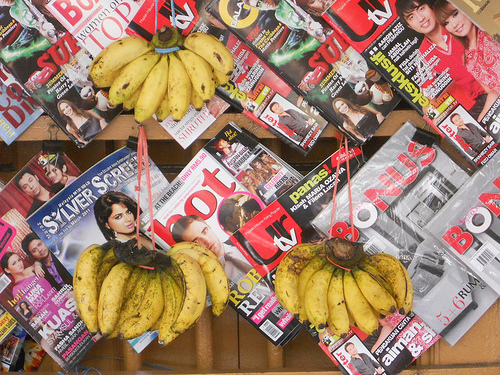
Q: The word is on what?
A: The word is on the magazine.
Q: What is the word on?
A: The word is on the magazine.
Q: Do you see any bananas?
A: Yes, there is a banana.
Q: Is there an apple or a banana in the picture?
A: Yes, there is a banana.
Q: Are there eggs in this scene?
A: No, there are no eggs.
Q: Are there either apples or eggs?
A: No, there are no eggs or apples.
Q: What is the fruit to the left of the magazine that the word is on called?
A: The fruit is a banana.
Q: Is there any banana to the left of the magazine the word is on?
A: Yes, there is a banana to the left of the magazine.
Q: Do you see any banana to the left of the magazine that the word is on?
A: Yes, there is a banana to the left of the magazine.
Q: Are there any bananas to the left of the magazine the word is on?
A: Yes, there is a banana to the left of the magazine.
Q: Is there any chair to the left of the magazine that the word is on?
A: No, there is a banana to the left of the magazine.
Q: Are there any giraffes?
A: No, there are no giraffes.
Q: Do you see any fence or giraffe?
A: No, there are no giraffes or fences.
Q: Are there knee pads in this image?
A: No, there are no knee pads.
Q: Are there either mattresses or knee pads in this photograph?
A: No, there are no knee pads or mattresses.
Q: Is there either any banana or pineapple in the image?
A: Yes, there is a banana.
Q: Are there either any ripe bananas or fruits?
A: Yes, there is a ripe banana.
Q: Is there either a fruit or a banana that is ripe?
A: Yes, the banana is ripe.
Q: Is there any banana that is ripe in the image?
A: Yes, there is a ripe banana.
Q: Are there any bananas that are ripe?
A: Yes, there is a banana that is ripe.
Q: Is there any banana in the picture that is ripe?
A: Yes, there is a banana that is ripe.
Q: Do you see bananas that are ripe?
A: Yes, there is a banana that is ripe.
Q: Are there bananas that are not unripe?
A: Yes, there is an ripe banana.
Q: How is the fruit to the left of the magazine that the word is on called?
A: The fruit is a banana.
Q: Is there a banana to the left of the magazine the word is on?
A: Yes, there is a banana to the left of the magazine.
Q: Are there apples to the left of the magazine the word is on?
A: No, there is a banana to the left of the magazine.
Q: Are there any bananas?
A: Yes, there is a banana.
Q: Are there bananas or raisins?
A: Yes, there is a banana.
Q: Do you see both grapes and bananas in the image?
A: No, there is a banana but no grapes.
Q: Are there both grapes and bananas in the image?
A: No, there is a banana but no grapes.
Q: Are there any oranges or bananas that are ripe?
A: Yes, the banana is ripe.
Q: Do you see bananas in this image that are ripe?
A: Yes, there is a ripe banana.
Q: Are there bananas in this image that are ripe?
A: Yes, there is a banana that is ripe.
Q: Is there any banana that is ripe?
A: Yes, there is a banana that is ripe.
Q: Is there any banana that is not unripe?
A: Yes, there is an ripe banana.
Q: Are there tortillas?
A: No, there are no tortillas.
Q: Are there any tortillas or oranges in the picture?
A: No, there are no tortillas or oranges.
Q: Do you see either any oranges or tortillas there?
A: No, there are no tortillas or oranges.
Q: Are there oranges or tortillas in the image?
A: No, there are no tortillas or oranges.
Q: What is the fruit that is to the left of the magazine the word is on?
A: The fruit is a banana.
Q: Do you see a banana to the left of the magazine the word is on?
A: Yes, there is a banana to the left of the magazine.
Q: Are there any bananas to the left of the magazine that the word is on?
A: Yes, there is a banana to the left of the magazine.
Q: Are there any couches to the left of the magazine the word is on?
A: No, there is a banana to the left of the magazine.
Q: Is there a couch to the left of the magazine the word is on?
A: No, there is a banana to the left of the magazine.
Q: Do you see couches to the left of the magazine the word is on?
A: No, there is a banana to the left of the magazine.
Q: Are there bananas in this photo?
A: Yes, there is a banana.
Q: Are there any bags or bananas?
A: Yes, there is a banana.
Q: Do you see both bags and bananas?
A: No, there is a banana but no bags.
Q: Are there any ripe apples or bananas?
A: Yes, there is a ripe banana.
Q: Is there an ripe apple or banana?
A: Yes, there is a ripe banana.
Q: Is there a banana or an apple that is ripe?
A: Yes, the banana is ripe.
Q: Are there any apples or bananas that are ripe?
A: Yes, the banana is ripe.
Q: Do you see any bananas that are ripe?
A: Yes, there is a ripe banana.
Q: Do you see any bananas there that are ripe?
A: Yes, there is a banana that is ripe.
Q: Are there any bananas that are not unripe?
A: Yes, there is an ripe banana.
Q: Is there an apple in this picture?
A: No, there are no apples.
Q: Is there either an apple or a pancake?
A: No, there are no apples or pancakes.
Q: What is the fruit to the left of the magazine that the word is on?
A: The fruit is a banana.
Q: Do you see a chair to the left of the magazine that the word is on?
A: No, there is a banana to the left of the magazine.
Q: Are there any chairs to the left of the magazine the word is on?
A: No, there is a banana to the left of the magazine.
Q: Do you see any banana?
A: Yes, there is a banana.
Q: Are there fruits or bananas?
A: Yes, there is a banana.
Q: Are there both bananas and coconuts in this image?
A: No, there is a banana but no coconuts.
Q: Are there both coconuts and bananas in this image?
A: No, there is a banana but no coconuts.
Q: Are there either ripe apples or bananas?
A: Yes, there is a ripe banana.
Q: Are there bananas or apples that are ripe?
A: Yes, the banana is ripe.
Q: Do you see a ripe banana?
A: Yes, there is a ripe banana.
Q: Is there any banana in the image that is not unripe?
A: Yes, there is an ripe banana.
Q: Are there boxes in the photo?
A: No, there are no boxes.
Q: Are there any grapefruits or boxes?
A: No, there are no boxes or grapefruits.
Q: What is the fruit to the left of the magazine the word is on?
A: The fruit is a banana.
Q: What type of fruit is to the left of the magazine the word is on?
A: The fruit is a banana.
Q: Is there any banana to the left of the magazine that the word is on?
A: Yes, there is a banana to the left of the magazine.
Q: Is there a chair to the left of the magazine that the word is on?
A: No, there is a banana to the left of the magazine.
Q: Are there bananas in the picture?
A: Yes, there are bananas.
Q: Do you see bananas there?
A: Yes, there are bananas.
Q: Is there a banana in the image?
A: Yes, there are bananas.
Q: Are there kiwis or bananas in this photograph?
A: Yes, there are bananas.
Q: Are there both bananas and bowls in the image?
A: No, there are bananas but no bowls.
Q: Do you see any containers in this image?
A: No, there are no containers.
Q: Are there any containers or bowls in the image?
A: No, there are no containers or bowls.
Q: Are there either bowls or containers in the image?
A: No, there are no containers or bowls.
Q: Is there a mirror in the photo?
A: No, there are no mirrors.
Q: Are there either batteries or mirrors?
A: No, there are no mirrors or batteries.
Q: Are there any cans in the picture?
A: No, there are no cans.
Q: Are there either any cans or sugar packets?
A: No, there are no cans or sugar packets.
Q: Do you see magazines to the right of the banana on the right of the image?
A: Yes, there is a magazine to the right of the banana.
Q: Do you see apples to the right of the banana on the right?
A: No, there is a magazine to the right of the banana.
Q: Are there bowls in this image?
A: No, there are no bowls.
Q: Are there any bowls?
A: No, there are no bowls.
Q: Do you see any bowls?
A: No, there are no bowls.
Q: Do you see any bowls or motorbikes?
A: No, there are no bowls or motorbikes.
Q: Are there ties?
A: Yes, there is a tie.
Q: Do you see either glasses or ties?
A: Yes, there is a tie.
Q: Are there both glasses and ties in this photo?
A: No, there is a tie but no glasses.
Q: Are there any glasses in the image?
A: No, there are no glasses.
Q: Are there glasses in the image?
A: No, there are no glasses.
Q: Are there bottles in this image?
A: No, there are no bottles.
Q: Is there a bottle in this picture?
A: No, there are no bottles.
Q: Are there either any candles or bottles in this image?
A: No, there are no bottles or candles.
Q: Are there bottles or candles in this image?
A: No, there are no bottles or candles.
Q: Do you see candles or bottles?
A: No, there are no bottles or candles.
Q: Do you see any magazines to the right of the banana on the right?
A: Yes, there are magazines to the right of the banana.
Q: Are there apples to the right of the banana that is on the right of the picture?
A: No, there are magazines to the right of the banana.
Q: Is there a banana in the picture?
A: Yes, there is a banana.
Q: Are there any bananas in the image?
A: Yes, there is a banana.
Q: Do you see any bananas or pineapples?
A: Yes, there is a banana.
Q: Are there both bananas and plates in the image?
A: No, there is a banana but no plates.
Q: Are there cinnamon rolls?
A: No, there are no cinnamon rolls.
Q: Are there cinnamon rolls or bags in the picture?
A: No, there are no cinnamon rolls or bags.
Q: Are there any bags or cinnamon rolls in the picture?
A: No, there are no cinnamon rolls or bags.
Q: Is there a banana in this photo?
A: Yes, there is a banana.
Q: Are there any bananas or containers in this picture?
A: Yes, there is a banana.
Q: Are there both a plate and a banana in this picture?
A: No, there is a banana but no plates.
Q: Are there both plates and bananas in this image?
A: No, there is a banana but no plates.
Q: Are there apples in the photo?
A: No, there are no apples.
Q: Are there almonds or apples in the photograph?
A: No, there are no apples or almonds.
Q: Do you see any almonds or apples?
A: No, there are no apples or almonds.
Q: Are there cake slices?
A: No, there are no cake slices.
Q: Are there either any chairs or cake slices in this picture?
A: No, there are no cake slices or chairs.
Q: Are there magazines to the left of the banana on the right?
A: Yes, there are magazines to the left of the banana.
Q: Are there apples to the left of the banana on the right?
A: No, there are magazines to the left of the banana.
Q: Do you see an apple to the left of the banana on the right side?
A: No, there are magazines to the left of the banana.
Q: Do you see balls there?
A: No, there are no balls.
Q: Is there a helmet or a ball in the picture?
A: No, there are no balls or helmets.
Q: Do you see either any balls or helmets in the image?
A: No, there are no balls or helmets.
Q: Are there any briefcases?
A: No, there are no briefcases.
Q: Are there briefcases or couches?
A: No, there are no briefcases or couches.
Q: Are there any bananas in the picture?
A: Yes, there are bananas.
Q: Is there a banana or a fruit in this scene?
A: Yes, there are bananas.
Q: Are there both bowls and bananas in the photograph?
A: No, there are bananas but no bowls.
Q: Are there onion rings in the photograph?
A: No, there are no onion rings.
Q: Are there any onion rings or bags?
A: No, there are no onion rings or bags.